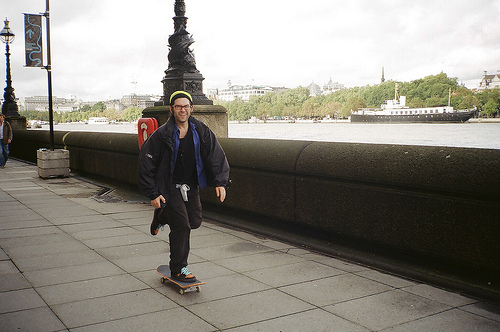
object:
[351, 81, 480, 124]
boat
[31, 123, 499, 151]
water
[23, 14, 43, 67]
lines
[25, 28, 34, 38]
arrow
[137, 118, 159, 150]
object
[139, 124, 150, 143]
white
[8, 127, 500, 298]
bridge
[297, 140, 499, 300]
part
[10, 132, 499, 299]
wall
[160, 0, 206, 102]
statue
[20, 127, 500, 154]
edge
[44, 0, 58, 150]
pole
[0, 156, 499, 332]
walkway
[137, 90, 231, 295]
man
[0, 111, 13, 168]
person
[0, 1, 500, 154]
background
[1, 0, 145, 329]
left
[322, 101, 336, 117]
trees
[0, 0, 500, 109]
distance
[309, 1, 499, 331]
right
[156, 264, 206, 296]
skateboard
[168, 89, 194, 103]
beanie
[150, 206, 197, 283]
sneakers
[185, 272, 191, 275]
laces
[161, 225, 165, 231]
laces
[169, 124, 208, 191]
shirt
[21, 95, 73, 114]
buildings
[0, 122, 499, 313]
sidewalk and river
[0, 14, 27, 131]
light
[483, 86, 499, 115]
trees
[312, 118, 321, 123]
boats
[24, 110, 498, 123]
shore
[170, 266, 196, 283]
foot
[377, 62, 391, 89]
tower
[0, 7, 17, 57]
top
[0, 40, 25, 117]
pole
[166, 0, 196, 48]
lamp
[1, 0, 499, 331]
visible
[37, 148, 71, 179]
box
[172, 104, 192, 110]
eyeglasses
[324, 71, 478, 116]
hills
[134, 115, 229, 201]
jacket